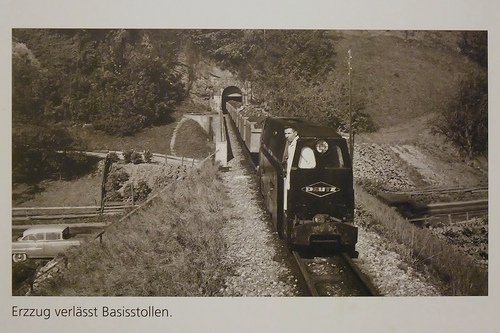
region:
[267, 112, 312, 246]
a man in the train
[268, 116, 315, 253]
a man in the train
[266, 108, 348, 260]
a man in the train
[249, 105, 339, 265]
a man in the train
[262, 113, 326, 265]
a man in the train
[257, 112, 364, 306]
a man in the train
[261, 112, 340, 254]
a man in the train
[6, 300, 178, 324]
Foreign language caption at bottom of photo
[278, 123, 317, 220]
Man standing out of car of train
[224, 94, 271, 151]
train cars full of a product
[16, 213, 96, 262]
Old fashioned car driving under a bridge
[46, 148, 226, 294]
Grass growing on side of track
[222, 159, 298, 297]
Gravel on side of tracks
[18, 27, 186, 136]
Trees and shrubs to left of tracks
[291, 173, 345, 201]
Logo of manufacturer of train car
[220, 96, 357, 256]
the long train on the track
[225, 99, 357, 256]
the old fashioned train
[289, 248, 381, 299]
the track in front of the train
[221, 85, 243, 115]
the tunnel for the train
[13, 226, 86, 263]
the old fashioned car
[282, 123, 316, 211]
the man on the train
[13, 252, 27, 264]
the tire on the car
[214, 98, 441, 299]
the rocks around the track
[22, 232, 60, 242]
the windows on the car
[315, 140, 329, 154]
the light on the train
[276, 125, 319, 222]
a man in a white shirt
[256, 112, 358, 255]
a man in a train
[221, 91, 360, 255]
a long old train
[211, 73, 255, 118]
a tunnel in some rocks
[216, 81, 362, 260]
a train going into a tunnel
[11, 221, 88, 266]
an old car on the road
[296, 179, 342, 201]
a logo on a train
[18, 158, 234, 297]
a bunch of grass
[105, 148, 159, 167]
a row of bushes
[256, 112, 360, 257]
a black train car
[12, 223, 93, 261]
chevy car passing under bridge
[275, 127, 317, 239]
man standing at door of train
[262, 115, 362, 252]
small black train on tracks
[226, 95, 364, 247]
small train pulling carts of coal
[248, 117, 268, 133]
coal loaded in train cart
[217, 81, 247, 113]
opening to tunnel in mountain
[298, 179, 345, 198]
white logo on front of train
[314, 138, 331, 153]
glass headlight on train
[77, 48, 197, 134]
trees on side of the mountain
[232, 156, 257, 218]
gravel beside train tracks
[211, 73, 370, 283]
a narrow train in train tracks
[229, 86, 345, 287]
a narrow train in train tracks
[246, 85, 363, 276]
a narrow train in train tracks